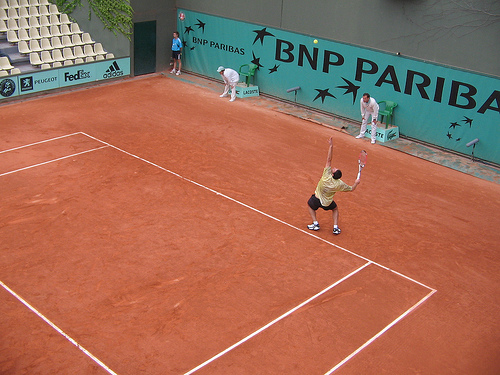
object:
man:
[304, 136, 367, 236]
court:
[0, 139, 109, 225]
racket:
[355, 146, 370, 181]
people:
[350, 89, 388, 149]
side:
[261, 82, 357, 123]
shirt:
[313, 169, 346, 205]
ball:
[311, 37, 321, 45]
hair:
[335, 172, 342, 179]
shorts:
[307, 193, 338, 211]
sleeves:
[320, 166, 334, 176]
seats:
[3, 30, 21, 44]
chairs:
[28, 52, 45, 68]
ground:
[124, 98, 165, 137]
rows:
[7, 23, 84, 44]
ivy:
[105, 0, 131, 22]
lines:
[80, 130, 107, 145]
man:
[213, 65, 242, 102]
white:
[227, 74, 237, 80]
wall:
[183, 12, 216, 73]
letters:
[272, 38, 295, 63]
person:
[167, 27, 187, 78]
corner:
[157, 1, 196, 77]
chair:
[239, 62, 257, 85]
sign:
[270, 37, 500, 118]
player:
[298, 133, 375, 237]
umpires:
[215, 60, 240, 102]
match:
[206, 60, 379, 238]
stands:
[0, 0, 130, 76]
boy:
[165, 32, 187, 77]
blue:
[172, 41, 177, 49]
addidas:
[102, 58, 125, 79]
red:
[363, 154, 369, 164]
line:
[137, 158, 204, 188]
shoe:
[307, 221, 321, 231]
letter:
[321, 50, 345, 74]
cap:
[216, 65, 226, 73]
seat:
[0, 53, 18, 72]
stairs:
[5, 45, 28, 73]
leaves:
[113, 30, 119, 35]